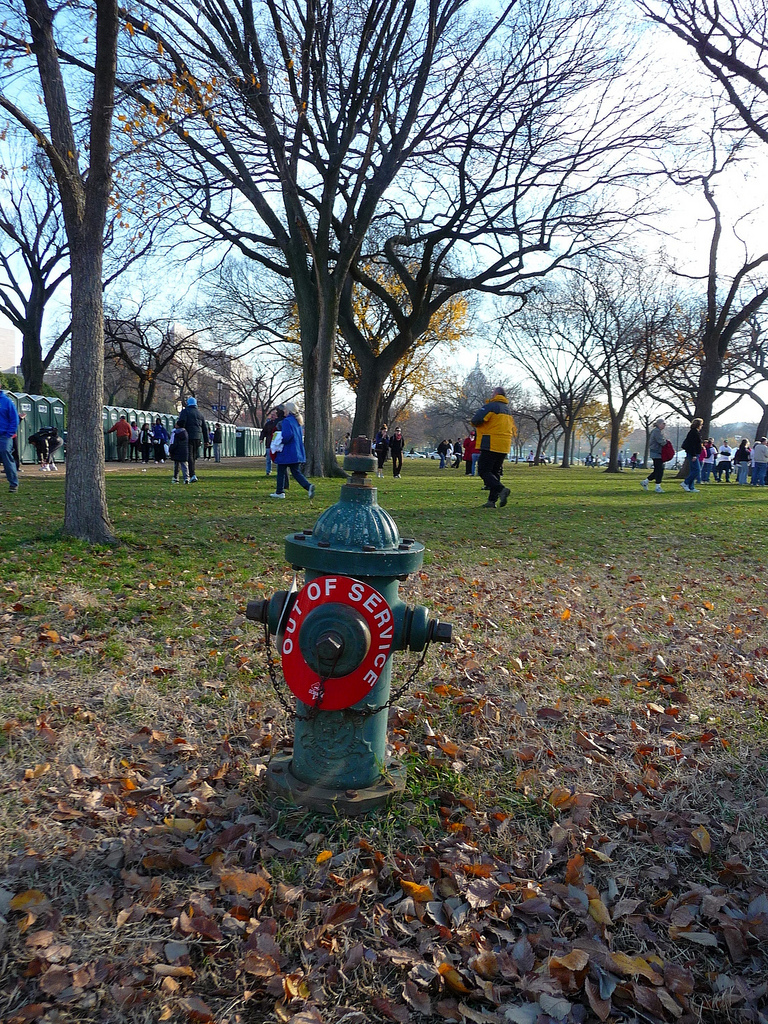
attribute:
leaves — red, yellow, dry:
[87, 745, 672, 999]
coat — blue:
[264, 403, 305, 460]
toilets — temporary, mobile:
[2, 391, 73, 462]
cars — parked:
[391, 439, 498, 469]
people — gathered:
[24, 410, 220, 468]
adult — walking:
[182, 418, 236, 476]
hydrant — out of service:
[256, 445, 452, 735]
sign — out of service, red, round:
[260, 582, 461, 703]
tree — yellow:
[323, 261, 546, 393]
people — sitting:
[503, 441, 561, 473]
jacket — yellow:
[454, 386, 550, 464]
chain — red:
[224, 639, 458, 728]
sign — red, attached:
[249, 566, 415, 705]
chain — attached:
[235, 615, 332, 723]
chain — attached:
[348, 594, 515, 747]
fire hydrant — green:
[248, 444, 435, 779]